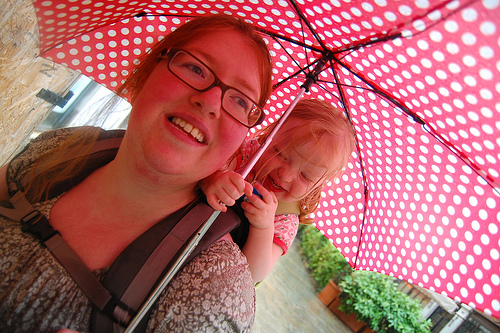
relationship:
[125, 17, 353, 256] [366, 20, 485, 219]
people under an umbrella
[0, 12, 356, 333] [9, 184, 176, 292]
people has straps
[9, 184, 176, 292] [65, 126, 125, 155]
straps on shoulders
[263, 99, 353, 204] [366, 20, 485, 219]
little girl holding umbrella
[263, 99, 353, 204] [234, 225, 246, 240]
little girl on back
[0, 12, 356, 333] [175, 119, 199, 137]
people has teeth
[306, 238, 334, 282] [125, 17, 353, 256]
bushes behind people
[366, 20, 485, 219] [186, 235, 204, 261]
umbrella has a handle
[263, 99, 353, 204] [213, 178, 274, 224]
little girl has hands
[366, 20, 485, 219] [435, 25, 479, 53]
umbrella has polka dots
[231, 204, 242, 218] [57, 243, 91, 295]
back pack has a strap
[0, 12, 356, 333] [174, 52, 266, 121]
people has glasses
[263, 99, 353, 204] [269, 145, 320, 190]
little girl has a face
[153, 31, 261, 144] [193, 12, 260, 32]
head has hair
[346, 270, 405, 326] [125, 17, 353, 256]
plants behind people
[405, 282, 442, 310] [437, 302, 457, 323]
gate has a hinge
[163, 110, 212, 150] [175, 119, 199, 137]
mouth has teeth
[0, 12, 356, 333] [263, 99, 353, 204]
people carrying child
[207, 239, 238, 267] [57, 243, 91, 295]
shoulder has a strap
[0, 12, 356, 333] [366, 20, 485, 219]
people holding umbrella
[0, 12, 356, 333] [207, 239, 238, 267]
people has a shoulder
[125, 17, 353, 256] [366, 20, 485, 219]
people under umbrella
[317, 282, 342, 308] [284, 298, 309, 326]
planter on ground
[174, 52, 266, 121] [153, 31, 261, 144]
glasses on face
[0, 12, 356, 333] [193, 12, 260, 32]
people has hair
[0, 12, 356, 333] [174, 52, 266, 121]
people has eyes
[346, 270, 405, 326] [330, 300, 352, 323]
plants in pots